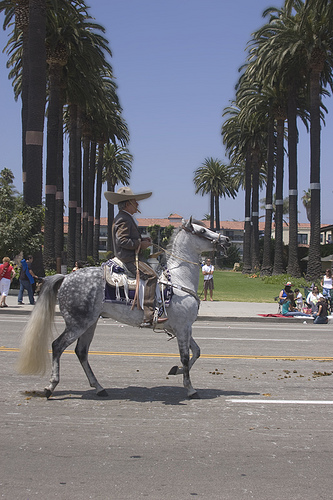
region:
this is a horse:
[65, 273, 101, 317]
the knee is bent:
[188, 342, 203, 359]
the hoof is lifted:
[165, 362, 183, 380]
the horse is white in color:
[172, 236, 207, 283]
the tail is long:
[14, 295, 57, 378]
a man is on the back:
[97, 182, 158, 292]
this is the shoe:
[157, 317, 168, 324]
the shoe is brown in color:
[155, 313, 167, 321]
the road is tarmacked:
[190, 395, 287, 492]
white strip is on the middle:
[292, 391, 321, 409]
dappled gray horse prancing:
[30, 185, 231, 419]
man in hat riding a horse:
[36, 172, 228, 397]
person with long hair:
[252, 291, 311, 320]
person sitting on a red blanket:
[253, 288, 313, 321]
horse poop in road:
[206, 343, 331, 390]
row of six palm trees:
[226, 25, 329, 279]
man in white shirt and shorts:
[199, 257, 226, 300]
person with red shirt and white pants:
[1, 246, 17, 308]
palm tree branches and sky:
[85, 23, 136, 149]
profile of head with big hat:
[101, 178, 157, 221]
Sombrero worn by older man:
[100, 184, 156, 207]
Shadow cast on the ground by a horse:
[19, 380, 266, 406]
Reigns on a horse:
[134, 235, 218, 268]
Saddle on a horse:
[100, 251, 174, 309]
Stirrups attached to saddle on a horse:
[137, 291, 166, 338]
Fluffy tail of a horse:
[12, 273, 74, 378]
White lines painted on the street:
[222, 390, 329, 421]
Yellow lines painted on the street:
[233, 351, 323, 371]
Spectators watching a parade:
[267, 280, 332, 315]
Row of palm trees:
[226, 100, 298, 277]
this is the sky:
[130, 21, 211, 123]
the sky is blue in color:
[156, 25, 195, 74]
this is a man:
[106, 183, 154, 262]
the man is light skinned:
[127, 204, 131, 211]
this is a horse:
[170, 220, 213, 352]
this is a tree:
[197, 154, 232, 211]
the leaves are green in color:
[210, 168, 225, 187]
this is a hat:
[113, 189, 137, 200]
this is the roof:
[143, 217, 178, 227]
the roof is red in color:
[223, 221, 238, 224]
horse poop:
[263, 346, 322, 396]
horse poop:
[243, 356, 318, 436]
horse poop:
[263, 366, 311, 417]